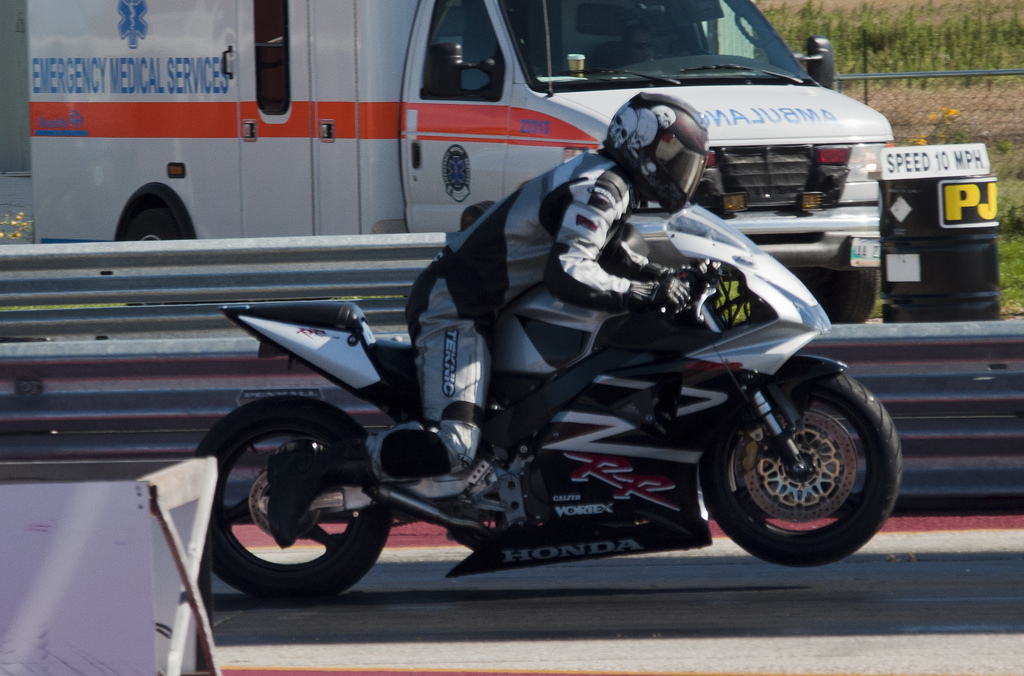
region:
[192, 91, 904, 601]
man riding on a motorcycle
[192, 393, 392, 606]
black tire on a motorcycle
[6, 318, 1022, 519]
metal railing along race track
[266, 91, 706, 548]
rider is dressed in protective gear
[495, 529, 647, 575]
manufacturer name painted on motorcycle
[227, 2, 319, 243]
door on the side of an ambulance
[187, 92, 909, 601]
the man is racing on a motorcycle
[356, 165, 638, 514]
the racer has a protective suit on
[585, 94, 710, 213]
the man has a full face helmet on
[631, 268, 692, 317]
the man is wearing racing gloves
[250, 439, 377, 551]
the cyclist is wearing racing boots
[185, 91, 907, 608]
the racer has popped a wheelie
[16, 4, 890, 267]
emergency vehicles are waiting near the track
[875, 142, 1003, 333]
signs are on a black barrel outside the track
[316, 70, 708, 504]
a man on a motorcycle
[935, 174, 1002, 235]
a yellow PJ on the barrel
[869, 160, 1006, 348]
a black barrel with yellow PJ on it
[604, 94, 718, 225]
a black helmet with skulls on it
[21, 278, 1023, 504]
a silver guard rail next to the bike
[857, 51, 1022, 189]
a fence next to the emergency vehicle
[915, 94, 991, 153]
yellow flowers on the other side of the fence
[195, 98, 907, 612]
the motorcyclist has popped a wheelie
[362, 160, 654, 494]
the man is wearing a protective jumpsuit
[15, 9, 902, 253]
emergency vehicles are at trackside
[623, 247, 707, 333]
the racer is wearing leather gloves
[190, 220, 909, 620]
the bike is black and white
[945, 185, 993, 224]
The letters PJ in yellow.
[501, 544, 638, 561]
The word HONDA on the bike.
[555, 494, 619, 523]
The word vortex on the bike.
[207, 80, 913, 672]
The man riding the bike.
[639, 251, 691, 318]
The mans hands in gloves.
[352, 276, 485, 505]
The mans motorcycle pants.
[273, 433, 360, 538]
The black leather boot.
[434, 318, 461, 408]
The logo on the pants.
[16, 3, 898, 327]
ambulance driving down street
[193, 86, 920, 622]
person riding black and grey motorcycle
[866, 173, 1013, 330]
black metal can with yellow letters on it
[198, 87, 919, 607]
man riding on a motorcycle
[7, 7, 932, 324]
ambulance riding down the road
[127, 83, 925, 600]
man on his commute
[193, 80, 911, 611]
racing down the road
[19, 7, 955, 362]
ambulance parked on a street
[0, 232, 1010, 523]
guard rail blocking the road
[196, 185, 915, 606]
motorcycle is doing tricks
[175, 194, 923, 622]
motorcycle going over the speed limit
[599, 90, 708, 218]
black full face helmet with skulls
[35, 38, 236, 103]
emergency medical service written on ambulance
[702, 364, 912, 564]
front wheel of bike off pavement in wheelie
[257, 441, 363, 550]
black lug heeled boot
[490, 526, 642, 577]
Honda written on side of bike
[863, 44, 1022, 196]
chain link fence at side of road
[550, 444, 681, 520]
red letters RR painted on bike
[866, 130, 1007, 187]
speed limit sign on barrel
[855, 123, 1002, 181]
speed limit sign on barrel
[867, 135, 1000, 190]
speed limit sign on barrel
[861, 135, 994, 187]
speed limit sign on barrel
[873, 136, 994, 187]
speed limit sign on barrel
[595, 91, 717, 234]
the head of a man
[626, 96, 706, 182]
the helmet of a man